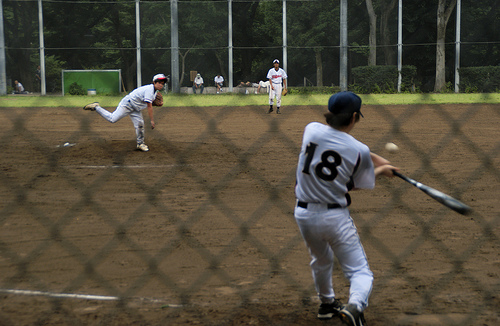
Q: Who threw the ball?
A: The pitcher.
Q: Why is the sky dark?
A: It is night time.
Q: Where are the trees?
A: Outside of the fence.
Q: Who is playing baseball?
A: The boys are playing.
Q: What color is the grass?
A: Green.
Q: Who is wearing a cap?
A: The baseball players.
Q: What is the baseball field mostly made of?
A: Dirt.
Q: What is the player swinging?
A: A bat.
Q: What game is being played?
A: Baseball.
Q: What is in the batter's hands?
A: Bat.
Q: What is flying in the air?
A: Ball.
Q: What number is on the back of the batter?
A: 18.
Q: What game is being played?
A: Baseball.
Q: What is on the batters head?
A: Hat.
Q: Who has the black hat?
A: Batter.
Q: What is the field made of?
A: Dirt.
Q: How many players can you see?
A: Three.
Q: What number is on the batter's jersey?
A: 18.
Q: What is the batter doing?
A: Swinging bat.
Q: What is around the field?
A: Fence.